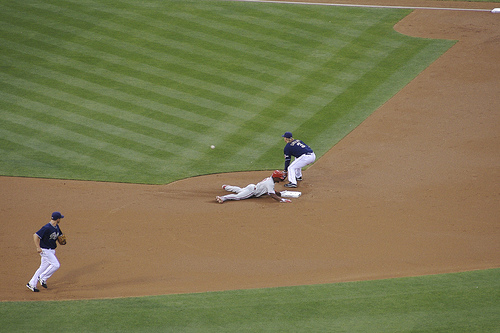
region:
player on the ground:
[215, 168, 309, 223]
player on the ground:
[206, 157, 298, 219]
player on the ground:
[201, 168, 286, 214]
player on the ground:
[194, 163, 306, 217]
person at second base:
[270, 110, 330, 190]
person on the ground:
[207, 160, 292, 220]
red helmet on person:
[261, 162, 292, 189]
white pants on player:
[28, 243, 68, 297]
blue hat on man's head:
[43, 204, 70, 223]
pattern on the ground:
[36, 59, 216, 164]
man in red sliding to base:
[220, 169, 302, 204]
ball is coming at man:
[210, 128, 315, 188]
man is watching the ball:
[25, 207, 68, 288]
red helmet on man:
[218, 170, 288, 205]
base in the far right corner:
[487, 5, 497, 12]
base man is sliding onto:
[278, 187, 298, 194]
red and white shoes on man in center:
[215, 181, 229, 206]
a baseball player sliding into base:
[215, 169, 302, 204]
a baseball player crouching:
[280, 130, 317, 190]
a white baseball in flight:
[209, 144, 214, 149]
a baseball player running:
[25, 211, 66, 295]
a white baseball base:
[279, 189, 301, 199]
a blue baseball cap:
[50, 210, 65, 219]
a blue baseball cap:
[280, 130, 292, 139]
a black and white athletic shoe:
[25, 282, 38, 292]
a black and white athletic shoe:
[36, 275, 47, 287]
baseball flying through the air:
[205, 143, 218, 150]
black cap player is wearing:
[49, 210, 64, 221]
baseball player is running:
[25, 210, 69, 291]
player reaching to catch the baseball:
[280, 132, 315, 185]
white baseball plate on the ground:
[277, 187, 301, 198]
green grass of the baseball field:
[0, 0, 457, 185]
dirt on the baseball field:
[0, 0, 498, 301]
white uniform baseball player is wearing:
[223, 176, 275, 199]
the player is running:
[15, 203, 76, 288]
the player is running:
[20, 200, 85, 300]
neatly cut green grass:
[1, 4, 456, 184]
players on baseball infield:
[0, 2, 497, 332]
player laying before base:
[216, 170, 302, 205]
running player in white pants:
[26, 211, 67, 292]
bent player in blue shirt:
[279, 132, 314, 187]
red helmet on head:
[272, 169, 287, 184]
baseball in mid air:
[209, 143, 216, 152]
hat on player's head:
[51, 211, 64, 226]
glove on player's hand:
[57, 232, 66, 246]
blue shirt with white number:
[285, 139, 312, 159]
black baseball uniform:
[224, 182, 272, 200]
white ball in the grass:
[204, 139, 221, 153]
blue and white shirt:
[34, 225, 64, 250]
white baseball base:
[281, 190, 301, 198]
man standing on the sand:
[280, 128, 313, 184]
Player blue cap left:
[51, 208, 64, 221]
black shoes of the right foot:
[27, 283, 37, 293]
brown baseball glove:
[59, 236, 69, 246]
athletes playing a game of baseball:
[0, 0, 499, 322]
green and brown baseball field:
[2, 3, 495, 332]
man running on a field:
[25, 208, 69, 292]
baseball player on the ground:
[215, 168, 295, 205]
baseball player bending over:
[277, 128, 316, 187]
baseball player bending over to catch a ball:
[205, 129, 320, 204]